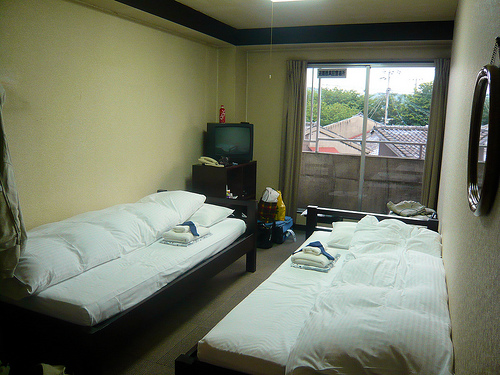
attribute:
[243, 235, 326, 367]
bed — white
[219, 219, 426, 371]
bed — white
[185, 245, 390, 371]
bed — white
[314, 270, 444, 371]
pillows — white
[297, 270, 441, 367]
pillow — white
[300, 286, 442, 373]
pillow — white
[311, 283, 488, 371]
pillow — white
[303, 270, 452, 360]
pillow — white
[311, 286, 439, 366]
pillow — white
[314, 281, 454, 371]
pillow — white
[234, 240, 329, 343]
bed — white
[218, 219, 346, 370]
bed — white